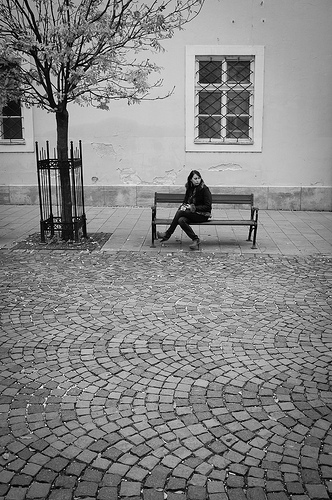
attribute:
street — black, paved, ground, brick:
[2, 250, 331, 498]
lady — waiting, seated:
[155, 169, 213, 252]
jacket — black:
[186, 184, 214, 213]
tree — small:
[2, 1, 210, 241]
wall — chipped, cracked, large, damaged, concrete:
[1, 1, 329, 212]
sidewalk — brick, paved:
[0, 205, 331, 257]